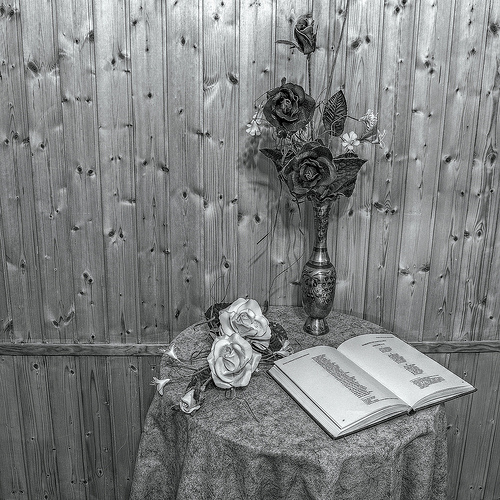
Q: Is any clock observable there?
A: No, there are no clocks.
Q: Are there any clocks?
A: No, there are no clocks.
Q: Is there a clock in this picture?
A: No, there are no clocks.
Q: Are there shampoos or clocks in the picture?
A: No, there are no clocks or shampoos.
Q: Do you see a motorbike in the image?
A: No, there are no motorcycles.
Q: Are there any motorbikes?
A: No, there are no motorbikes.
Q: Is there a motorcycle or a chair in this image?
A: No, there are no motorcycles or chairs.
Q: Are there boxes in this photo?
A: No, there are no boxes.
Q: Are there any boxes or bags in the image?
A: No, there are no boxes or bags.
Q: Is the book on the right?
A: Yes, the book is on the right of the image.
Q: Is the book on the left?
A: No, the book is on the right of the image.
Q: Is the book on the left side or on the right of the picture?
A: The book is on the right of the image.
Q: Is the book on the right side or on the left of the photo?
A: The book is on the right of the image.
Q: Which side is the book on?
A: The book is on the right of the image.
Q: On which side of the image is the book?
A: The book is on the right of the image.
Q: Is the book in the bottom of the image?
A: Yes, the book is in the bottom of the image.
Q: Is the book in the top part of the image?
A: No, the book is in the bottom of the image.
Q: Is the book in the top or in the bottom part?
A: The book is in the bottom of the image.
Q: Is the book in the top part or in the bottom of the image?
A: The book is in the bottom of the image.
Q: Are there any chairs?
A: No, there are no chairs.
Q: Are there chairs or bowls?
A: No, there are no chairs or bowls.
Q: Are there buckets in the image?
A: No, there are no buckets.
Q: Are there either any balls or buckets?
A: No, there are no buckets or balls.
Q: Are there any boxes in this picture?
A: No, there are no boxes.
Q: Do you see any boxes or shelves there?
A: No, there are no boxes or shelves.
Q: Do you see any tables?
A: Yes, there is a table.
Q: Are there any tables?
A: Yes, there is a table.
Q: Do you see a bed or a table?
A: Yes, there is a table.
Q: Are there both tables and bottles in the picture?
A: No, there is a table but no bottles.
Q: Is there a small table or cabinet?
A: Yes, there is a small table.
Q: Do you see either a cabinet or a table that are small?
A: Yes, the table is small.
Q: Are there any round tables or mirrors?
A: Yes, there is a round table.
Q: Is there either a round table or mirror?
A: Yes, there is a round table.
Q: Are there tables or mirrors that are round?
A: Yes, the table is round.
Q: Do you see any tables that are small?
A: Yes, there is a small table.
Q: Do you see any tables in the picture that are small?
A: Yes, there is a table that is small.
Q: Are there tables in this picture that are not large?
A: Yes, there is a small table.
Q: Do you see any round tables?
A: Yes, there is a round table.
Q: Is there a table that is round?
A: Yes, there is a table that is round.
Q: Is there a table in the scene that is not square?
A: Yes, there is a round table.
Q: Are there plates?
A: No, there are no plates.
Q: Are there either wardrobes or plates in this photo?
A: No, there are no plates or wardrobes.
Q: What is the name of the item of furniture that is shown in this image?
A: The piece of furniture is a table.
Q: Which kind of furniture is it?
A: The piece of furniture is a table.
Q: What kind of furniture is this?
A: This is a table.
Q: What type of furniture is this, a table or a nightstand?
A: This is a table.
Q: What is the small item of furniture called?
A: The piece of furniture is a table.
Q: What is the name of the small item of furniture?
A: The piece of furniture is a table.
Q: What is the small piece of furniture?
A: The piece of furniture is a table.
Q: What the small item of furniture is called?
A: The piece of furniture is a table.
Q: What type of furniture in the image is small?
A: The furniture is a table.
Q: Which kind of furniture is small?
A: The furniture is a table.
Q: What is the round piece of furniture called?
A: The piece of furniture is a table.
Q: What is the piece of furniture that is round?
A: The piece of furniture is a table.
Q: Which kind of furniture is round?
A: The furniture is a table.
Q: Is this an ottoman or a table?
A: This is a table.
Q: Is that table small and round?
A: Yes, the table is small and round.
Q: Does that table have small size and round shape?
A: Yes, the table is small and round.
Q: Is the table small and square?
A: No, the table is small but round.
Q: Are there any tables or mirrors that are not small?
A: No, there is a table but it is small.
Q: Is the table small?
A: Yes, the table is small.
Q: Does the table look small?
A: Yes, the table is small.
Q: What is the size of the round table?
A: The table is small.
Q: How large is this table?
A: The table is small.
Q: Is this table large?
A: No, the table is small.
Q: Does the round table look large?
A: No, the table is small.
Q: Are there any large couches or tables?
A: No, there is a table but it is small.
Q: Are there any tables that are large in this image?
A: No, there is a table but it is small.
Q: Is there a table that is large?
A: No, there is a table but it is small.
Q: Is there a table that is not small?
A: No, there is a table but it is small.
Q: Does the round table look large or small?
A: The table is small.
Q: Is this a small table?
A: Yes, this is a small table.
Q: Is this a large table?
A: No, this is a small table.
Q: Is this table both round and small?
A: Yes, the table is round and small.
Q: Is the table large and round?
A: No, the table is round but small.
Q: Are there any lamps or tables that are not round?
A: No, there is a table but it is round.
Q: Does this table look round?
A: Yes, the table is round.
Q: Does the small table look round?
A: Yes, the table is round.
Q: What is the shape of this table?
A: The table is round.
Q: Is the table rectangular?
A: No, the table is round.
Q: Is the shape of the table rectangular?
A: No, the table is round.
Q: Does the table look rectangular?
A: No, the table is round.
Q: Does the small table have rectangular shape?
A: No, the table is round.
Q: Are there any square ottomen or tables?
A: No, there is a table but it is round.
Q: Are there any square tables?
A: No, there is a table but it is round.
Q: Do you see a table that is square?
A: No, there is a table but it is round.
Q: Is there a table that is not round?
A: No, there is a table but it is round.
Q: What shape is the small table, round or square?
A: The table is round.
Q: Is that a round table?
A: Yes, that is a round table.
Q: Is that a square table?
A: No, that is a round table.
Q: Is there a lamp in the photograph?
A: No, there are no lamps.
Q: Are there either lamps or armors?
A: No, there are no lamps or armors.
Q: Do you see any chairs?
A: No, there are no chairs.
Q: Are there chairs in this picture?
A: No, there are no chairs.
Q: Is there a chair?
A: No, there are no chairs.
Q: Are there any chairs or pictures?
A: No, there are no chairs or pictures.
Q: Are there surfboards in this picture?
A: No, there are no surfboards.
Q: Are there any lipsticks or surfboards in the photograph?
A: No, there are no surfboards or lipsticks.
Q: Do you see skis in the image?
A: No, there are no skis.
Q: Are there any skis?
A: No, there are no skis.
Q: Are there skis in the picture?
A: No, there are no skis.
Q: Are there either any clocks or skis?
A: No, there are no skis or clocks.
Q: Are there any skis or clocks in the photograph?
A: No, there are no skis or clocks.